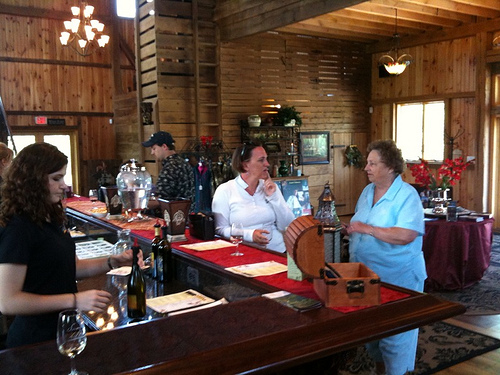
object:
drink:
[89, 267, 133, 322]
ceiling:
[16, 6, 480, 44]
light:
[379, 18, 411, 78]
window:
[386, 99, 451, 165]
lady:
[344, 141, 427, 364]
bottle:
[122, 245, 147, 325]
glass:
[54, 305, 93, 370]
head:
[146, 125, 179, 160]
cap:
[139, 132, 179, 148]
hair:
[4, 140, 66, 214]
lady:
[0, 141, 116, 359]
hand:
[76, 287, 109, 312]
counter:
[44, 178, 479, 371]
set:
[426, 187, 485, 218]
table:
[424, 221, 484, 289]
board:
[139, 84, 160, 105]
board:
[137, 66, 159, 82]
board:
[140, 56, 160, 72]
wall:
[256, 42, 364, 75]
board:
[137, 25, 158, 42]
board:
[138, 82, 163, 100]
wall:
[0, 0, 138, 124]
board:
[134, 0, 161, 22]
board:
[285, 239, 299, 254]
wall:
[287, 211, 327, 272]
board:
[298, 212, 323, 234]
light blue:
[373, 206, 414, 231]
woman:
[211, 142, 298, 254]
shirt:
[214, 175, 297, 249]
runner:
[64, 180, 424, 332]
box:
[284, 217, 387, 317]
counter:
[7, 185, 472, 373]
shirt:
[351, 174, 428, 288]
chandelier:
[57, 5, 119, 55]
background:
[0, 0, 142, 222]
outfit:
[350, 177, 428, 370]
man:
[147, 122, 205, 222]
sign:
[32, 112, 67, 126]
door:
[4, 133, 84, 197]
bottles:
[154, 221, 172, 296]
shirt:
[0, 203, 80, 342]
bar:
[11, 179, 472, 372]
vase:
[409, 150, 467, 205]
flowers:
[398, 150, 468, 200]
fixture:
[370, 42, 436, 82]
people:
[131, 118, 431, 278]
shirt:
[151, 153, 203, 210]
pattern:
[179, 161, 190, 173]